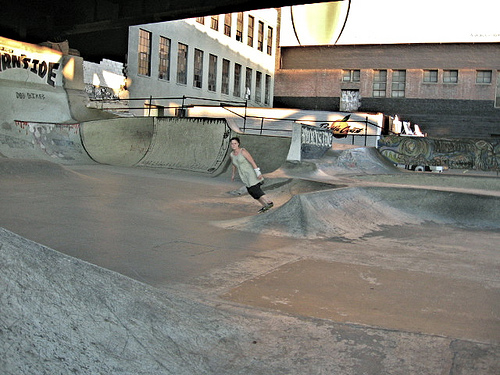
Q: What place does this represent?
A: It represents the skate park.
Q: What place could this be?
A: It is a skate park.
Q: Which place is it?
A: It is a skate park.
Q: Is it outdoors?
A: Yes, it is outdoors.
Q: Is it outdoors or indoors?
A: It is outdoors.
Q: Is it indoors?
A: No, it is outdoors.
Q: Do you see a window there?
A: Yes, there is a window.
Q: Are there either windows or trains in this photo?
A: Yes, there is a window.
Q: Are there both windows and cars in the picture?
A: No, there is a window but no cars.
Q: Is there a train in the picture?
A: No, there are no trains.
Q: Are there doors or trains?
A: No, there are no trains or doors.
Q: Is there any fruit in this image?
A: Yes, there is a fruit.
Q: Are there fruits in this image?
A: Yes, there is a fruit.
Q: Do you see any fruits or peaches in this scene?
A: Yes, there is a fruit.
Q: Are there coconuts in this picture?
A: No, there are no coconuts.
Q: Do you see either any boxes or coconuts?
A: No, there are no coconuts or boxes.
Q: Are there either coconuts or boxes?
A: No, there are no coconuts or boxes.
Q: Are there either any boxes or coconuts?
A: No, there are no coconuts or boxes.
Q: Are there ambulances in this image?
A: No, there are no ambulances.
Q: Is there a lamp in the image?
A: No, there are no lamps.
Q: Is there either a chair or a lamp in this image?
A: No, there are no lamps or chairs.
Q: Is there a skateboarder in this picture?
A: Yes, there is a skateboarder.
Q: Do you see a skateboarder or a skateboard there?
A: Yes, there is a skateboarder.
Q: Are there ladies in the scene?
A: No, there are no ladies.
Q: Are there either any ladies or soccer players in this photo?
A: No, there are no ladies or soccer players.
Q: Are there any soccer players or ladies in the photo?
A: No, there are no ladies or soccer players.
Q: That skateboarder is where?
A: The skateboarder is in the skate park.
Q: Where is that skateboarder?
A: The skateboarder is in the skate park.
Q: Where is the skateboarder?
A: The skateboarder is in the skate park.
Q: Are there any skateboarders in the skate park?
A: Yes, there is a skateboarder in the skate park.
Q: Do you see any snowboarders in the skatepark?
A: No, there is a skateboarder in the skatepark.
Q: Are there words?
A: Yes, there are words.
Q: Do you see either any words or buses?
A: Yes, there are words.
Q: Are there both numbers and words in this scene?
A: No, there are words but no numbers.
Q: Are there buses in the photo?
A: No, there are no buses.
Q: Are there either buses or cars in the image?
A: No, there are no buses or cars.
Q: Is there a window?
A: Yes, there are windows.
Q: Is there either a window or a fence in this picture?
A: Yes, there are windows.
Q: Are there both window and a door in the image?
A: No, there are windows but no doors.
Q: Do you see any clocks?
A: No, there are no clocks.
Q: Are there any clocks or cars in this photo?
A: No, there are no clocks or cars.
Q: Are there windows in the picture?
A: Yes, there are windows.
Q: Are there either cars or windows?
A: Yes, there are windows.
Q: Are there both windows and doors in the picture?
A: No, there are windows but no doors.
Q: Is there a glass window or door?
A: Yes, there are glass windows.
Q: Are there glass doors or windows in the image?
A: Yes, there are glass windows.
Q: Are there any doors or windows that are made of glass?
A: Yes, the windows are made of glass.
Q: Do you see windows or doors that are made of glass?
A: Yes, the windows are made of glass.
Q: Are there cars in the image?
A: No, there are no cars.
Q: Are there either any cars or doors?
A: No, there are no cars or doors.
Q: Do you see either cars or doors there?
A: No, there are no cars or doors.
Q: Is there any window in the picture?
A: Yes, there is a window.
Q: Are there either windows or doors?
A: Yes, there is a window.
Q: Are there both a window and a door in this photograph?
A: No, there is a window but no doors.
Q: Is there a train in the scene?
A: No, there are no trains.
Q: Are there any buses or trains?
A: No, there are no trains or buses.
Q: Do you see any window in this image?
A: Yes, there is a window.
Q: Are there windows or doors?
A: Yes, there is a window.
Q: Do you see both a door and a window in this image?
A: No, there is a window but no doors.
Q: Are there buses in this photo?
A: No, there are no buses.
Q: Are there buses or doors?
A: No, there are no buses or doors.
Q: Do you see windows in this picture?
A: Yes, there is a window.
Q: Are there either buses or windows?
A: Yes, there is a window.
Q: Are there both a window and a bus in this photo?
A: No, there is a window but no buses.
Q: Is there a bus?
A: No, there are no buses.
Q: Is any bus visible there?
A: No, there are no buses.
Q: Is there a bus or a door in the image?
A: No, there are no buses or doors.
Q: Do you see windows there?
A: Yes, there is a window.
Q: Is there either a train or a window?
A: Yes, there is a window.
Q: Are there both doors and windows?
A: No, there is a window but no doors.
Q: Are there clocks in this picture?
A: No, there are no clocks.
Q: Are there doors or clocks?
A: No, there are no clocks or doors.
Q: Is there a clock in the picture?
A: No, there are no clocks.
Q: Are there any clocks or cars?
A: No, there are no clocks or cars.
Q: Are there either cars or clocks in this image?
A: No, there are no clocks or cars.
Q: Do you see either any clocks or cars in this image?
A: No, there are no clocks or cars.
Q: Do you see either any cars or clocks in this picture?
A: No, there are no clocks or cars.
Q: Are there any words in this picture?
A: Yes, there are words.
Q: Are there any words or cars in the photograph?
A: Yes, there are words.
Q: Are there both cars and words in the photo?
A: No, there are words but no cars.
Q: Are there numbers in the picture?
A: No, there are no numbers.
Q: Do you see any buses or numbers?
A: No, there are no numbers or buses.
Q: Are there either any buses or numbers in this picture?
A: No, there are no numbers or buses.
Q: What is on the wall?
A: The words are on the wall.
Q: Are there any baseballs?
A: No, there are no baseballs.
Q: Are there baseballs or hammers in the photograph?
A: No, there are no baseballs or hammers.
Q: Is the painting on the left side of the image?
A: Yes, the painting is on the left of the image.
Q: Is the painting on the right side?
A: No, the painting is on the left of the image.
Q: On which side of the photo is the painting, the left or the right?
A: The painting is on the left of the image.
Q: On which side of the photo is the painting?
A: The painting is on the left of the image.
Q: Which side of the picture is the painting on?
A: The painting is on the left of the image.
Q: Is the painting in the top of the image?
A: Yes, the painting is in the top of the image.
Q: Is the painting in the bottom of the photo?
A: No, the painting is in the top of the image.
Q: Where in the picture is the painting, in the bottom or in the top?
A: The painting is in the top of the image.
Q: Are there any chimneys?
A: No, there are no chimneys.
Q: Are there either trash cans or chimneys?
A: No, there are no chimneys or trash cans.